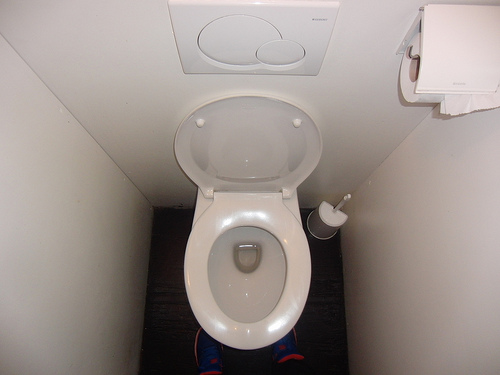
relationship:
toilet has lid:
[172, 92, 324, 351] [173, 92, 325, 201]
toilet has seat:
[172, 92, 324, 351] [183, 193, 313, 351]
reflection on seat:
[219, 210, 274, 229] [183, 193, 313, 351]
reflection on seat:
[267, 295, 299, 335] [183, 193, 313, 351]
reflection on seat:
[209, 318, 228, 331] [183, 193, 313, 351]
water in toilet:
[231, 239, 264, 277] [172, 92, 324, 351]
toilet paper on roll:
[399, 31, 500, 117] [408, 54, 421, 83]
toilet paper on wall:
[399, 31, 500, 117] [0, 1, 498, 209]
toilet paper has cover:
[399, 31, 500, 117] [395, 4, 499, 96]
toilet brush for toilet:
[332, 193, 353, 213] [172, 92, 324, 351]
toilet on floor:
[172, 92, 324, 351] [140, 204, 348, 374]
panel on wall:
[167, 1, 343, 77] [0, 1, 498, 209]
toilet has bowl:
[172, 92, 324, 351] [208, 225, 288, 323]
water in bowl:
[231, 239, 264, 277] [208, 225, 288, 323]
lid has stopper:
[173, 92, 325, 201] [196, 118, 205, 127]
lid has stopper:
[173, 92, 325, 201] [293, 118, 301, 126]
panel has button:
[167, 1, 343, 77] [256, 39, 306, 66]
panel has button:
[167, 1, 343, 77] [197, 12, 282, 67]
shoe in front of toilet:
[194, 326, 226, 374] [172, 92, 324, 351]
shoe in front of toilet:
[269, 326, 305, 373] [172, 92, 324, 351]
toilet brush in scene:
[332, 193, 353, 213] [1, 1, 499, 375]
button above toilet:
[256, 39, 306, 66] [172, 92, 324, 351]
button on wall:
[256, 39, 306, 66] [0, 1, 498, 209]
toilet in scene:
[172, 92, 324, 351] [1, 1, 499, 375]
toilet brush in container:
[332, 193, 353, 213] [306, 202, 349, 241]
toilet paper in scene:
[399, 31, 500, 117] [1, 1, 499, 375]